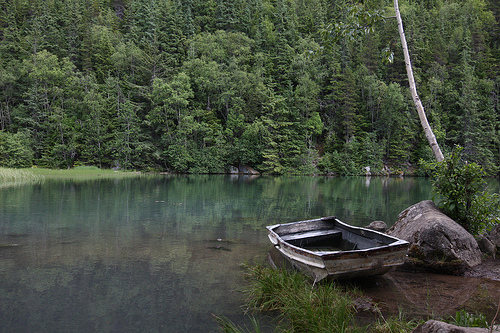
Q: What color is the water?
A: Blue.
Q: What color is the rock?
A: Gray.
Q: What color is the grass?
A: Green.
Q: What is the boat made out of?
A: Wood.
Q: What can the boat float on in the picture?
A: Water.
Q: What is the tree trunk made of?
A: Wood.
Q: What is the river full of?
A: Water.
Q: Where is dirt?
A: On riverside.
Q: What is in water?
A: Abandoned boat.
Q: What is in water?
A: Little water.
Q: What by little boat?
A: Big rock.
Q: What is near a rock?
A: Boat.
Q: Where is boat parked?
A: On shore.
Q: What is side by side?
A: Water and trees.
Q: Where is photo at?
A: Peaceful place.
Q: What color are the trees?
A: Green.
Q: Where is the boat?
A: By a rock.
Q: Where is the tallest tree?
A: Right over the water.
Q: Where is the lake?
A: Next to the woods.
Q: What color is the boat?
A: White.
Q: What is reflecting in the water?
A: Trees.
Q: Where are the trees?
A: All over the back of the lake.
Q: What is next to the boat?
A: A big rock.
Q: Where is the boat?
A: On the sand.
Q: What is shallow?
A: The water.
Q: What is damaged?
A: The boat.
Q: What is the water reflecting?
A: Trees.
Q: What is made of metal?
A: A boat.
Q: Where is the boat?
A: In the water.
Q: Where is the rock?
A: In the water.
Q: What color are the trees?
A: Green.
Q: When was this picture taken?
A: Day time.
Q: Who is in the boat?
A: Its empty.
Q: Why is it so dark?
A: The sun is not shining.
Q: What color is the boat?
A: White.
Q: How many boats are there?
A: One.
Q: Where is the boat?
A: Next to a big rock.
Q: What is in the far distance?
A: Trees.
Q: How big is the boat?
A: Small.